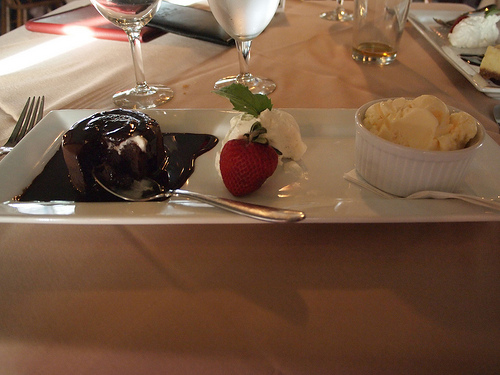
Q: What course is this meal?
A: Dessert.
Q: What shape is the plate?
A: Rectangle.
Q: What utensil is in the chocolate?
A: Spoon.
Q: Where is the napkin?
A: Under the bowl.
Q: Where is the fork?
A: Left of the plate.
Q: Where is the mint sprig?
A: In the whipped cream.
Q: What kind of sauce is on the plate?
A: Chocolate.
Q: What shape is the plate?
A: Rectangle.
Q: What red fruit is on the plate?
A: Strawberry.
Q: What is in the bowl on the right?
A: Ice cream.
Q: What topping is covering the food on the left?
A: Chocolate.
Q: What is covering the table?
A: Table cloth.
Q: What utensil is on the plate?
A: Spoon.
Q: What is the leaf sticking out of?
A: Whipped Cream.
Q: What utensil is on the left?
A: Fork.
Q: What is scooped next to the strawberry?
A: Whipped cream.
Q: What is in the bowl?
A: Icecream.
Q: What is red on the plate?
A: A strawberry.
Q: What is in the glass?
A: Water.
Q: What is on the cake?
A: Chocolate.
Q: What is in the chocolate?
A: A spoon.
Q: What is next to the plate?
A: A fork.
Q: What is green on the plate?
A: Mint.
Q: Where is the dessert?
A: On the table.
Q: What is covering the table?
A: A white tablecloth.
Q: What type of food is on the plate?
A: Dessert.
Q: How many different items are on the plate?
A: Three.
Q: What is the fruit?
A: Strawberry.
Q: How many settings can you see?
A: Two.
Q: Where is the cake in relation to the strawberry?
A: On the left.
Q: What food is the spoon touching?
A: The cake.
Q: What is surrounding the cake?
A: Chocolate sauce.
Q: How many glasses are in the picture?
A: Four.